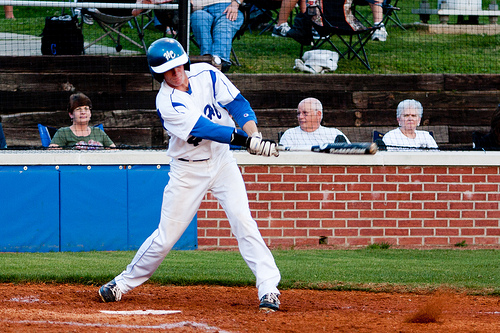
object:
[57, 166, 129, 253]
board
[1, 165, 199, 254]
padded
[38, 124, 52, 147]
chair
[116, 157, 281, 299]
trousers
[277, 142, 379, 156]
bat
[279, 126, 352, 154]
shirt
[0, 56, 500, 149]
wall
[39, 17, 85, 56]
black bag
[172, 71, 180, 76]
nose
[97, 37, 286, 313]
batter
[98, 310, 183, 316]
plate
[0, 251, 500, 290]
lawn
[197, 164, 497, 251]
wall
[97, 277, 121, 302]
cleats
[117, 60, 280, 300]
baseball uniform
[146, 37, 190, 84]
helmet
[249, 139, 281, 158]
gloves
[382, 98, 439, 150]
spectators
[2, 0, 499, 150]
background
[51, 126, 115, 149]
shirt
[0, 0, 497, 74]
fencing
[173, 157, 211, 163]
belt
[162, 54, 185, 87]
batter's head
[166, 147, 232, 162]
waist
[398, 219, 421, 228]
part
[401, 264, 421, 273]
part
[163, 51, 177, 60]
part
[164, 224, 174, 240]
part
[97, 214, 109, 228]
part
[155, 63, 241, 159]
jersey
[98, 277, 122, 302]
foot